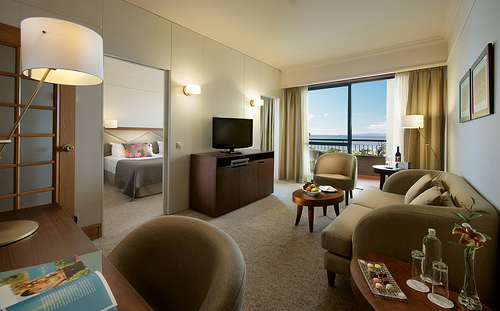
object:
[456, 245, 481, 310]
vase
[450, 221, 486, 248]
flower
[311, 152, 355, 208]
chair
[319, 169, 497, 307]
couch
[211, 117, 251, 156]
tv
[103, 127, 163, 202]
bed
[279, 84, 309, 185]
curtains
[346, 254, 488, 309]
table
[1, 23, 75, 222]
door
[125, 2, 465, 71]
ceiling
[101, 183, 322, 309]
floor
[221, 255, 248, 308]
edge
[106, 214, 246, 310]
chair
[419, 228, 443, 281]
bottle of water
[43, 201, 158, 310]
edge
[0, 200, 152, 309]
table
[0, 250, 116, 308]
magaine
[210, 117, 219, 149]
edge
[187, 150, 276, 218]
stand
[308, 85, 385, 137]
sky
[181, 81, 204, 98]
light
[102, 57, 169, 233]
room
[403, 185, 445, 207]
pillows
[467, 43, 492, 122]
pictures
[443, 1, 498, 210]
wall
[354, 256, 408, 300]
tray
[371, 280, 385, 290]
candies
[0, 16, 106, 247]
table lamp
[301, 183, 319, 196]
bowl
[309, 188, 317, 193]
fruits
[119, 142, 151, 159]
pillow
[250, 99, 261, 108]
wall light fixture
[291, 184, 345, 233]
coffee table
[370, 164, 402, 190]
side table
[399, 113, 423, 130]
lamp